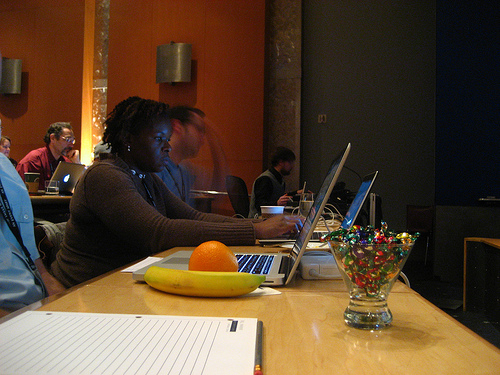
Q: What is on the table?
A: Computers.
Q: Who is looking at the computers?
A: Some people.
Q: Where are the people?
A: In a room.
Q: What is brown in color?
A: The table.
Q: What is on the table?
A: Food.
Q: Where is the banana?
A: Next to the orange.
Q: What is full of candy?
A: The glass.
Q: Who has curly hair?
A: The woman.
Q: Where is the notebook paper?
A: On the table.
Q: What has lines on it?
A: Paper.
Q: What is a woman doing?
A: Typing on laptop.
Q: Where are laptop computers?
A: On tables.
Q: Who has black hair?
A: The woman typing.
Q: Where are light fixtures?
A: On the wall.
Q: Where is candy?
A: In a bowl.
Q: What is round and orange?
A: The orange.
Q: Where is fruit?
A: Next to a laptop.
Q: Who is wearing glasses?
A: Man in red shirt.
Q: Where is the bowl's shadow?
A: On the table.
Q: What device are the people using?
A: Laptop.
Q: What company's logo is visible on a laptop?
A: Apple.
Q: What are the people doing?
A: Working on their computers.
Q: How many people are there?
A: Six.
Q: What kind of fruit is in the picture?
A: An orange and a banana.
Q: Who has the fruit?
A: The person in the blue shirt.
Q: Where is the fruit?
A: Next to a computer.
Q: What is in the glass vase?
A: Candy.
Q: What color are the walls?
A: Orange.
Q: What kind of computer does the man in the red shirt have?
A: A Mac.